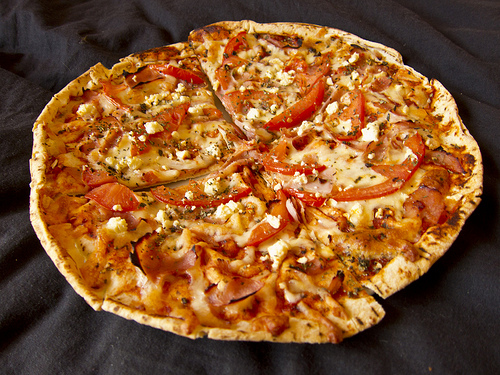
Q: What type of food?
A: Pizza.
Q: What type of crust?
A: Thin.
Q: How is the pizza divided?
A: Into four slices.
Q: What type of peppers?
A: Red.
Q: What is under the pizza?
A: Tablecloth.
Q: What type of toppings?
A: Meat and vegetables.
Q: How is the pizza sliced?
A: In four.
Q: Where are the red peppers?
A: On the pizza.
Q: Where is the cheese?
A: On the pizza.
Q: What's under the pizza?
A: Black cloth.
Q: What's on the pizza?
A: Tomatoes.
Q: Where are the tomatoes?
A: On the pizza.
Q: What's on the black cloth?
A: A pizza.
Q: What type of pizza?
A: Pita-type.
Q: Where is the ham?
A: On the pizza.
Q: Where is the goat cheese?
A: On the pizza.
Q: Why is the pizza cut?
A: For slices.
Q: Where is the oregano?
A: On the pizza.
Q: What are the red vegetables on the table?
A: Tomatoes.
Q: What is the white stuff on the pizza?
A: Cheese.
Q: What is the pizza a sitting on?
A: A cloth.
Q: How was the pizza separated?
A: Sliced.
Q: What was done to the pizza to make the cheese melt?
A: It was cooked.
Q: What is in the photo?
A: Pizza.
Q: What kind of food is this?
A: PIzza.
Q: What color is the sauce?
A: Red.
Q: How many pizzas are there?
A: One.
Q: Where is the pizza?
A: On a table.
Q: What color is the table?
A: Black.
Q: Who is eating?
A: There is no one eating.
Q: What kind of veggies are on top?
A: Peppers.